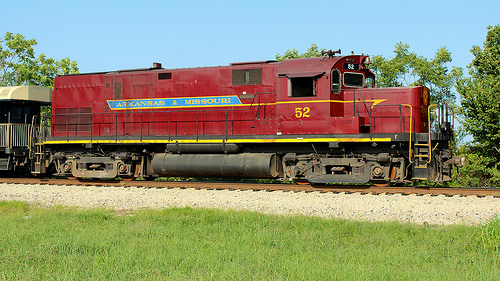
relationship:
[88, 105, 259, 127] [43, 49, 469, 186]
pain on train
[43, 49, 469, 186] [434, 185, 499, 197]
red train on tracks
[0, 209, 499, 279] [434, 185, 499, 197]
green grass next to tracks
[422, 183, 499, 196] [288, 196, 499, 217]
tracks are built on dirt and gravel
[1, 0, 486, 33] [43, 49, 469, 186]
blue sky above train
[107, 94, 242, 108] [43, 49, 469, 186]
business name on train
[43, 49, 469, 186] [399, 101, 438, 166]
train has yellow handrails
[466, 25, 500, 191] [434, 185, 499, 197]
green trees along tracks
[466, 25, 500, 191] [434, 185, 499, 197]
green trees bordering tracks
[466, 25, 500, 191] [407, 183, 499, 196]
green trees lining train tracks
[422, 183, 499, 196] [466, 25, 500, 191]
tracks are bordered by green trees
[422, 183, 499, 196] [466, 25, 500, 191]
tracks are lined by green trees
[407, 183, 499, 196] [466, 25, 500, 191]
train tracks are bordered by green trees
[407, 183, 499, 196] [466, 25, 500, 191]
train tracks are lined by green trees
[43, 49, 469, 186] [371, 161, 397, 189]
train has steel wheels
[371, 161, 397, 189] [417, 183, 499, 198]
train wheels are on track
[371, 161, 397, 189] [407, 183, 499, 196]
train wheels are on steel tracks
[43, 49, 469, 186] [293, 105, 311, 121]
train has an id number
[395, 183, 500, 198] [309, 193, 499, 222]
track built up with gravel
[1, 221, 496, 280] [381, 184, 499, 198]
grass field next to tracks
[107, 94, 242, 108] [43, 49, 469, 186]
name logo on train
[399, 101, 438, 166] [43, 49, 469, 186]
yellow handrails on train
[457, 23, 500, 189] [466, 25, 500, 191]
trees have green leaves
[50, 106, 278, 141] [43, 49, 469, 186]
safety rail on train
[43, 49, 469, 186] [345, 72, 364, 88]
train has a front windshield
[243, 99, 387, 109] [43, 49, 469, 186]
pin stripe on train engine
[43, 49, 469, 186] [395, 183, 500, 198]
train on steel tracks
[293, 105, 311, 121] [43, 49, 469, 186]
id number on train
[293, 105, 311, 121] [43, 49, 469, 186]
id number of train engine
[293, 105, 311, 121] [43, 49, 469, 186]
id number on train engine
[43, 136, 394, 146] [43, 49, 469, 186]
pin stripe on train engine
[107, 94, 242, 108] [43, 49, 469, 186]
name brand on train engine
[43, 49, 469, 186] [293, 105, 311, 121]
train engine has an id number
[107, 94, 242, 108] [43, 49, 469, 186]
name brand written on train engine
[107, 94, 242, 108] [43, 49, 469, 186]
brand name written on train engine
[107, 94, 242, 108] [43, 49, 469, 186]
company name written on train engine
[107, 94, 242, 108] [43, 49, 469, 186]
train route written on train engine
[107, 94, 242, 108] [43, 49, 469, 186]
company brand displayed on train engine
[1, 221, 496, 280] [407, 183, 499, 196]
green field next to train tracks